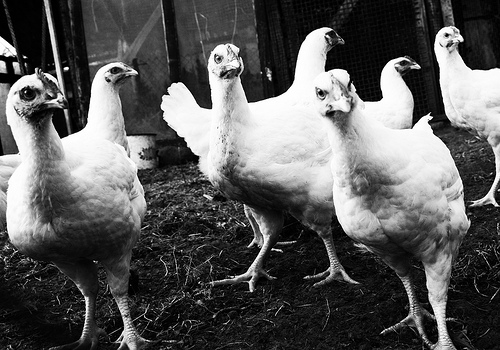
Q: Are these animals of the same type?
A: Yes, all the animals are chicken.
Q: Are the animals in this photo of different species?
A: No, all the animals are chicken.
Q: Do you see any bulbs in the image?
A: No, there are no bulbs.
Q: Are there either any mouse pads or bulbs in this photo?
A: No, there are no bulbs or mouse pads.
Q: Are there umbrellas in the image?
A: No, there are no umbrellas.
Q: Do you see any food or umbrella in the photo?
A: No, there are no umbrellas or food.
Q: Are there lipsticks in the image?
A: No, there are no lipsticks.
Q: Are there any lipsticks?
A: No, there are no lipsticks.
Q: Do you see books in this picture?
A: No, there are no books.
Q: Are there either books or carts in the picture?
A: No, there are no books or carts.